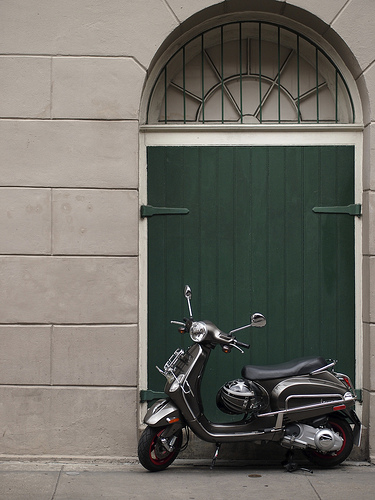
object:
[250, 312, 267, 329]
mirror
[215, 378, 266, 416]
helmet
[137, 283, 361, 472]
scooter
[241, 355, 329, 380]
seat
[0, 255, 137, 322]
bricks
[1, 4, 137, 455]
wall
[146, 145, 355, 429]
door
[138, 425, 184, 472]
wheel